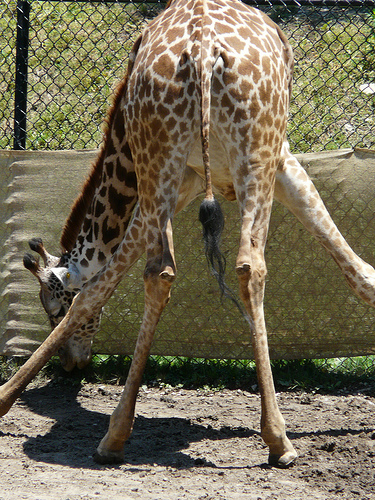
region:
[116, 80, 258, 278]
the giraffe has tail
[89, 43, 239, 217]
the giraffe has tail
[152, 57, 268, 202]
the giraffe has tail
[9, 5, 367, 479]
Giraffe eating grass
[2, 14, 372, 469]
Giraffe with feet spayed to trying to reach grass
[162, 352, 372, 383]
Green grass on the other side of the fence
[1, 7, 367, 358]
Metal fence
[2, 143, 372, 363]
Cloth lining bottom of a fence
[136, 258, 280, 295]
Knobby knees of a giraffe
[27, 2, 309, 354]
Giraffe mooning a photographer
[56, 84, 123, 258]
Orange mane on a giraffe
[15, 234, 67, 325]
Small horns on a giraffe's head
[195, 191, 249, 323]
Long black hair on the end of a giraffe' tail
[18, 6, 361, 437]
a giraffe with splayed legs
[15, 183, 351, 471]
a giraffe bending to eat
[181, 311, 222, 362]
a chain link fence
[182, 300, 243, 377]
clothe covering a chain link fence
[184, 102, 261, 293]
a giraffe's tail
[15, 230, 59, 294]
a giraffe's horns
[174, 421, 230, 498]
dirt and mud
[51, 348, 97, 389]
a giraffe sneaking grass from outside his enclosure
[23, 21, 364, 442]
a large animal on display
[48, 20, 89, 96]
a grassy slope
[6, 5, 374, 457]
a giraffe eating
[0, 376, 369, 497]
dirt in the giraffe containment area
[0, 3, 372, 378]
A chain link fence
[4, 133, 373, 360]
A cloth alongside the base of the fence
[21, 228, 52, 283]
The giraffe's horns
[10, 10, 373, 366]
A grassy area behind the fence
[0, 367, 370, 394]
some grass coming through the fence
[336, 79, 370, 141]
some rocks behind the fence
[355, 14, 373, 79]
the branches of a small bush behind the fence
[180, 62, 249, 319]
the giraffe's tail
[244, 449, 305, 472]
sand on giraffe's hoof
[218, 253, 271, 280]
knobbly knees on giraffe's calf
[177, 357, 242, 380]
green grass peeking under fence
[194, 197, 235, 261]
black bushy tail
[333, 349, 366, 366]
tiny white spot on green grass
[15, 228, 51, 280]
horns on top of giraffe's head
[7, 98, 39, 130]
green post on chain link fence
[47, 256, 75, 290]
giraffe's long white ears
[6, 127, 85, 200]
tan covering on fence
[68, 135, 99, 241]
brown mane on giraffe's back